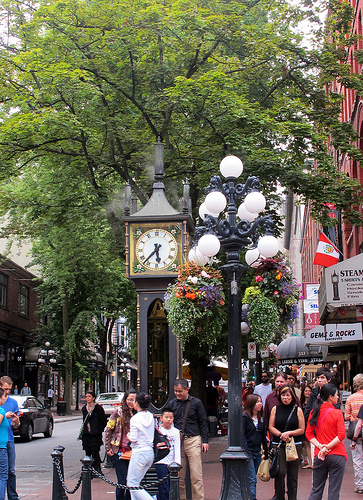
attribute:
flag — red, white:
[313, 226, 344, 271]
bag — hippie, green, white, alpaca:
[75, 399, 99, 439]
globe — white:
[218, 152, 244, 179]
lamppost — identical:
[36, 338, 57, 408]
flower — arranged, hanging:
[174, 269, 231, 306]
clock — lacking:
[134, 221, 183, 267]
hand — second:
[155, 241, 160, 265]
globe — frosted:
[219, 154, 243, 176]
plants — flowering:
[146, 258, 309, 352]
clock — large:
[134, 227, 177, 271]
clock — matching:
[122, 209, 188, 277]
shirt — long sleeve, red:
[306, 407, 344, 455]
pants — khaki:
[169, 431, 212, 497]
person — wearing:
[126, 391, 154, 498]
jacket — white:
[128, 410, 155, 452]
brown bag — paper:
[252, 432, 301, 483]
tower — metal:
[120, 136, 190, 428]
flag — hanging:
[313, 229, 344, 268]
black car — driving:
[9, 393, 54, 439]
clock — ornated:
[124, 219, 184, 275]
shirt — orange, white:
[343, 388, 361, 421]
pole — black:
[189, 153, 291, 273]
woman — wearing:
[306, 381, 345, 494]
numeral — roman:
[145, 230, 154, 241]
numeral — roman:
[153, 230, 162, 239]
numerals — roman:
[136, 226, 179, 273]